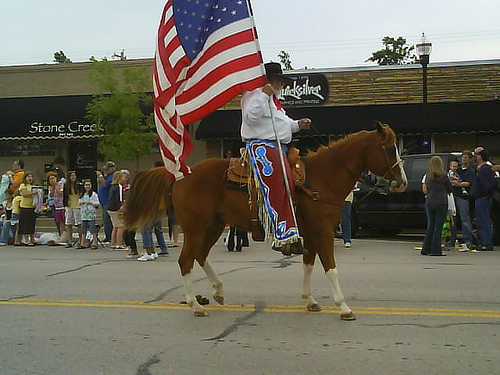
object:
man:
[240, 61, 310, 256]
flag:
[150, 0, 269, 180]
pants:
[239, 139, 304, 247]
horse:
[118, 122, 406, 321]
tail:
[117, 167, 175, 232]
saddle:
[224, 147, 307, 190]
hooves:
[212, 293, 225, 306]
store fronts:
[221, 103, 500, 185]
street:
[2, 249, 75, 269]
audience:
[0, 159, 99, 250]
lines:
[74, 296, 145, 308]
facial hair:
[267, 83, 282, 97]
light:
[416, 36, 432, 149]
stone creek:
[29, 119, 105, 135]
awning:
[0, 108, 22, 141]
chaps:
[239, 139, 305, 250]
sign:
[276, 73, 329, 107]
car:
[353, 153, 498, 238]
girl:
[74, 179, 101, 249]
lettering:
[275, 79, 324, 100]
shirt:
[240, 88, 300, 144]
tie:
[273, 94, 284, 111]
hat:
[264, 62, 283, 80]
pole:
[422, 63, 428, 86]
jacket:
[98, 174, 114, 205]